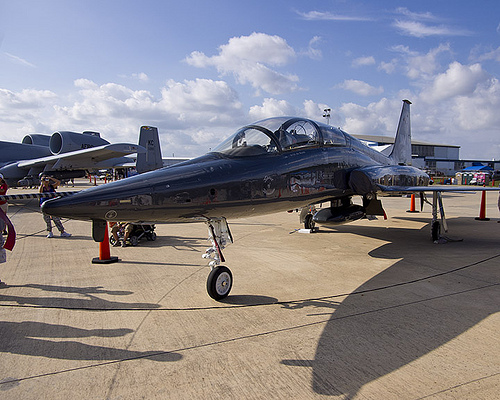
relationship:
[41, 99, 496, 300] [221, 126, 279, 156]
plane has windshield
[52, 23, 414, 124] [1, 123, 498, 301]
sky above airport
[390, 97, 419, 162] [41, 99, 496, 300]
tail wing on plane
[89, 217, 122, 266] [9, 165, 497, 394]
cone laying on ground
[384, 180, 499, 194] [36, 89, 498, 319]
wing on plane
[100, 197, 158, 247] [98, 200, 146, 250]
kid in stroller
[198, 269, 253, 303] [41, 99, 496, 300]
tire on plane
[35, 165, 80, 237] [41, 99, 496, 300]
person taking picture of plane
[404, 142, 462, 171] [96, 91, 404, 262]
building behind plane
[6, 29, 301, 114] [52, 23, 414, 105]
clouds in sky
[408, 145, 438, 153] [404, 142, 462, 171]
windows on building